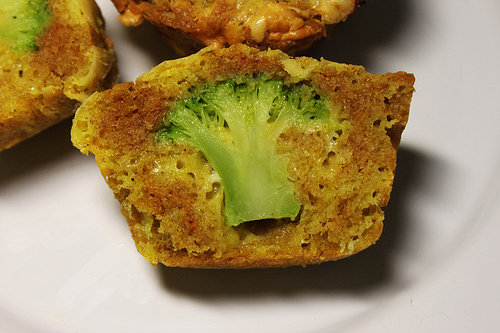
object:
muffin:
[351, 88, 391, 246]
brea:
[71, 46, 417, 267]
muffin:
[134, 56, 339, 81]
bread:
[92, 90, 159, 139]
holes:
[152, 219, 203, 264]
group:
[0, 0, 484, 265]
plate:
[16, 5, 485, 307]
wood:
[60, 296, 132, 329]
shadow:
[173, 266, 396, 302]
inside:
[250, 128, 268, 218]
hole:
[113, 185, 131, 205]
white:
[250, 181, 268, 216]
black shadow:
[399, 149, 424, 289]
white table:
[430, 114, 495, 152]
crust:
[244, 10, 267, 43]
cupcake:
[109, 0, 357, 47]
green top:
[277, 78, 325, 118]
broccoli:
[156, 76, 332, 229]